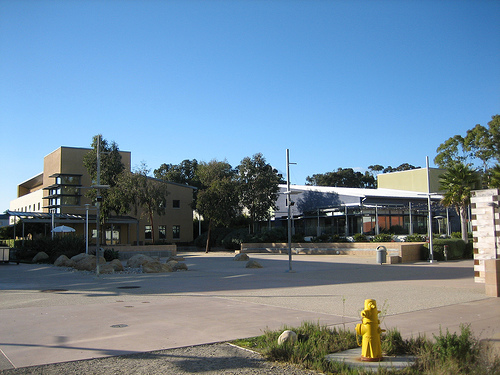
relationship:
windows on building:
[3, 168, 183, 241] [11, 146, 205, 250]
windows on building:
[265, 201, 455, 240] [271, 167, 472, 245]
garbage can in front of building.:
[374, 244, 388, 266] [38, 94, 465, 321]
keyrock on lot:
[143, 259, 164, 272] [0, 251, 499, 373]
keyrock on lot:
[53, 253, 72, 265] [0, 251, 499, 373]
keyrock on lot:
[128, 252, 155, 265] [0, 251, 499, 373]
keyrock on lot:
[172, 261, 188, 269] [0, 251, 499, 373]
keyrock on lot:
[165, 254, 182, 262] [0, 251, 499, 373]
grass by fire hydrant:
[298, 327, 333, 368] [353, 294, 389, 360]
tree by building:
[83, 151, 152, 243] [1, 144, 194, 266]